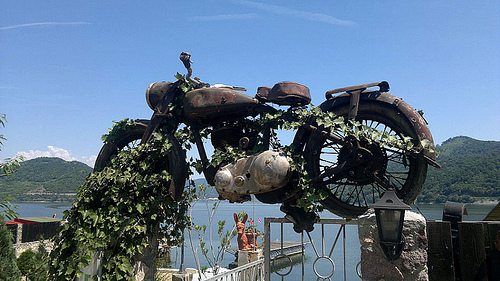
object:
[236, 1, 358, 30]
clouds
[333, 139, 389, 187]
wheel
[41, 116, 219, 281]
ivy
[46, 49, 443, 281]
archway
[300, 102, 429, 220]
wheel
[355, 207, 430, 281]
stone fence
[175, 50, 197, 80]
handles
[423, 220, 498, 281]
fence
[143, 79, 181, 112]
headlight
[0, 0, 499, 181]
sky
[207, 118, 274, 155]
gears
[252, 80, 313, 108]
seat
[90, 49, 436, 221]
bike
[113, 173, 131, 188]
leaves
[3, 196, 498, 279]
dock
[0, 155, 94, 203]
hill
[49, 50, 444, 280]
entryway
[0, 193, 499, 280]
lake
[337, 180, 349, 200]
spokes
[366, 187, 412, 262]
lamp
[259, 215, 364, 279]
gate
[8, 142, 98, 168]
clouds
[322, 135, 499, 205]
hills